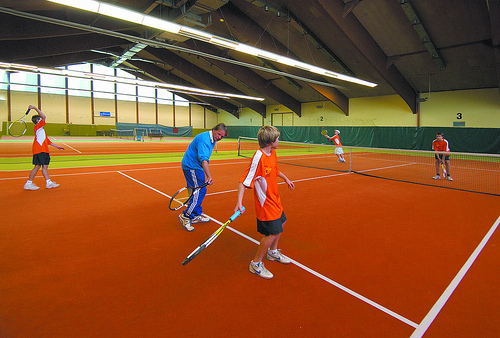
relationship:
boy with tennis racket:
[234, 123, 298, 279] [168, 175, 213, 212]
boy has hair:
[234, 123, 298, 279] [255, 125, 278, 147]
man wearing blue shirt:
[177, 122, 230, 234] [180, 128, 217, 172]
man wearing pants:
[177, 122, 230, 234] [181, 167, 206, 219]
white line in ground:
[114, 170, 438, 337] [0, 135, 499, 334]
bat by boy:
[183, 205, 245, 266] [237, 126, 294, 276]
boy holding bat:
[194, 123, 336, 293] [186, 199, 266, 257]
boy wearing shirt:
[234, 123, 298, 279] [245, 147, 297, 224]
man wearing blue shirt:
[168, 122, 235, 227] [180, 128, 214, 171]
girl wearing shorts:
[23, 149, 66, 191] [26, 145, 57, 171]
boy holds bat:
[234, 123, 298, 279] [178, 205, 249, 266]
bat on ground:
[178, 205, 249, 266] [0, 136, 500, 337]